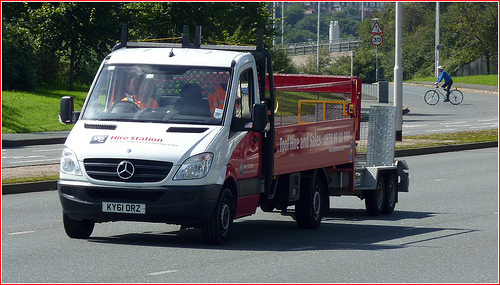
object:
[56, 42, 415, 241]
truck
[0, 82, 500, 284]
street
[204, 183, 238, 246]
tire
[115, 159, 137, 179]
emblem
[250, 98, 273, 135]
side mirror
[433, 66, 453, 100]
person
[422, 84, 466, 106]
bike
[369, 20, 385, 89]
sign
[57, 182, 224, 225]
bumper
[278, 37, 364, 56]
fence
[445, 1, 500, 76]
tree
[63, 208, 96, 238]
tire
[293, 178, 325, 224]
tire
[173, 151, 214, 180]
headlight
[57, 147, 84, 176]
headlight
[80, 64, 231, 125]
windshield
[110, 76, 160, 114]
man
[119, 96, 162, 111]
shirt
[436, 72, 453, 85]
shirt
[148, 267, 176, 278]
line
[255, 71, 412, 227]
trailer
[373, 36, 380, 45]
30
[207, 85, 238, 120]
safety jacket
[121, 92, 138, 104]
seat belt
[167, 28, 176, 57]
antenna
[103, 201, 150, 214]
license plate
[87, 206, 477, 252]
shade